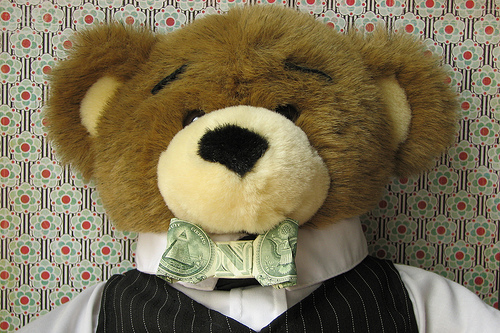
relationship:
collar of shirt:
[132, 215, 372, 293] [12, 214, 498, 331]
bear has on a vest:
[33, 11, 499, 293] [99, 270, 429, 332]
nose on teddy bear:
[204, 126, 275, 176] [138, 29, 367, 168]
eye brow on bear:
[149, 60, 189, 98] [33, 11, 499, 293]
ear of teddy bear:
[44, 27, 148, 187] [43, 25, 432, 230]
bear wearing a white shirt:
[33, 11, 499, 293] [3, 216, 498, 331]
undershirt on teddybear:
[6, 212, 499, 332] [16, 3, 497, 330]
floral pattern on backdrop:
[0, 185, 73, 277] [1, 3, 498, 331]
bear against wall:
[33, 11, 499, 293] [1, 0, 498, 330]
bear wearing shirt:
[33, 11, 499, 293] [12, 214, 498, 331]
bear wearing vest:
[33, 11, 499, 293] [93, 251, 421, 331]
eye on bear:
[273, 104, 298, 122] [33, 11, 499, 293]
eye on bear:
[180, 109, 202, 127] [33, 11, 499, 293]